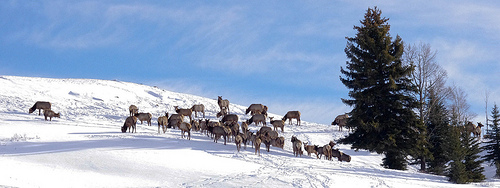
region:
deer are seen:
[166, 106, 307, 181]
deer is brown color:
[158, 101, 288, 180]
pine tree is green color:
[349, 18, 421, 161]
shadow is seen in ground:
[45, 114, 198, 159]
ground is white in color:
[33, 142, 88, 181]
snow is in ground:
[28, 132, 188, 183]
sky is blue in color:
[28, 16, 215, 56]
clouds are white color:
[196, 20, 328, 65]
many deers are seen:
[118, 76, 343, 155]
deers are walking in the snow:
[109, 79, 364, 186]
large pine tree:
[339, 6, 429, 165]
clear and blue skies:
[53, 11, 308, 71]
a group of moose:
[22, 90, 363, 155]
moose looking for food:
[25, 90, 75, 125]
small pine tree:
[379, 143, 410, 178]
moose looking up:
[208, 93, 234, 113]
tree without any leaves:
[409, 63, 446, 186]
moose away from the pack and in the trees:
[451, 111, 486, 137]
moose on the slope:
[205, 90, 235, 111]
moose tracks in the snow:
[256, 160, 324, 186]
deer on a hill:
[16, 60, 390, 163]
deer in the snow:
[21, 83, 356, 166]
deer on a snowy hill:
[23, 72, 356, 167]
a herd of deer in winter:
[8, 77, 360, 182]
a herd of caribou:
[20, 65, 365, 175]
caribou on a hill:
[5, 73, 367, 158]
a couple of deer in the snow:
[12, 89, 69, 136]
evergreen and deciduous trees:
[332, 4, 454, 183]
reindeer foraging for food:
[14, 74, 358, 171]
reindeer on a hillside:
[21, 84, 355, 175]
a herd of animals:
[107, 87, 354, 168]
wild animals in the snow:
[97, 71, 383, 176]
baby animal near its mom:
[27, 97, 64, 120]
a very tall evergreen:
[341, 4, 416, 179]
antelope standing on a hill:
[201, 88, 240, 113]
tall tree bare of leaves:
[393, 36, 458, 174]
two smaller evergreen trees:
[439, 99, 490, 186]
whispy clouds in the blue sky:
[25, 7, 330, 74]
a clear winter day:
[30, 24, 460, 175]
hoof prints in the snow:
[235, 155, 366, 181]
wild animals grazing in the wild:
[117, 96, 355, 164]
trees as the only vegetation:
[349, 5, 475, 157]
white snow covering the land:
[23, 142, 143, 186]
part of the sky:
[35, 5, 228, 55]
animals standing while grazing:
[124, 91, 276, 149]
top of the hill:
[14, 76, 126, 96]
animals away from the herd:
[28, 99, 64, 121]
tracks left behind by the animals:
[214, 154, 295, 186]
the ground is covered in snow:
[8, 136, 101, 186]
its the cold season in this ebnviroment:
[24, 141, 173, 173]